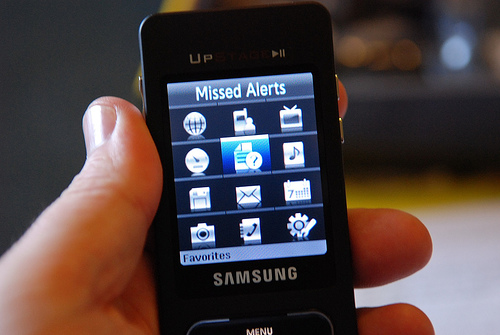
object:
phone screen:
[165, 76, 328, 267]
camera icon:
[189, 222, 215, 244]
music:
[282, 141, 305, 168]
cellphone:
[138, 1, 355, 335]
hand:
[3, 75, 437, 335]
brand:
[213, 266, 297, 285]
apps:
[184, 112, 207, 136]